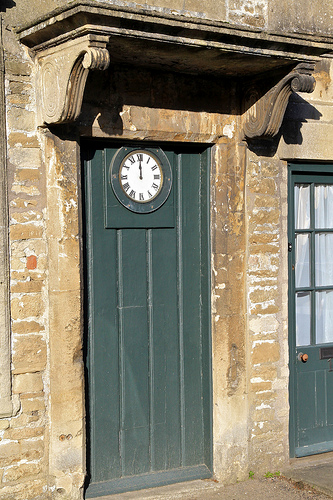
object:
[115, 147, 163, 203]
clock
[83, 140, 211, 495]
door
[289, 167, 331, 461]
door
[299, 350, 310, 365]
handle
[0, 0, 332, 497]
building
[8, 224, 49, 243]
brick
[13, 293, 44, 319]
brick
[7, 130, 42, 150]
brick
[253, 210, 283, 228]
brick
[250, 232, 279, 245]
brick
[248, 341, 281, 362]
brick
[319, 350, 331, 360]
slot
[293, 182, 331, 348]
window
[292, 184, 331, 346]
curtain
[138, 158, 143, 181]
hand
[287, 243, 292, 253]
doorbell